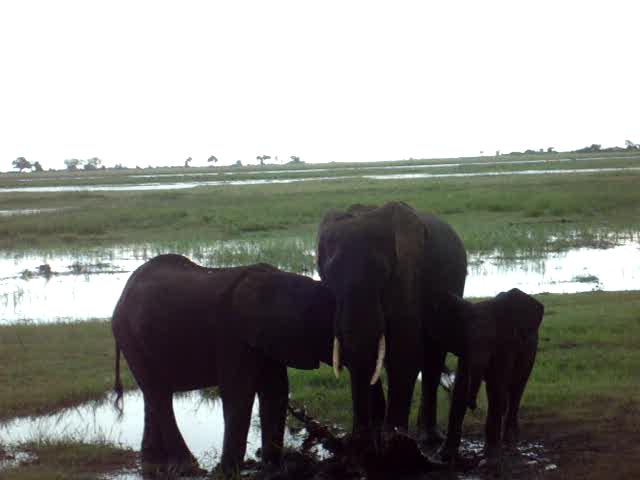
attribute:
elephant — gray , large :
[465, 286, 550, 467]